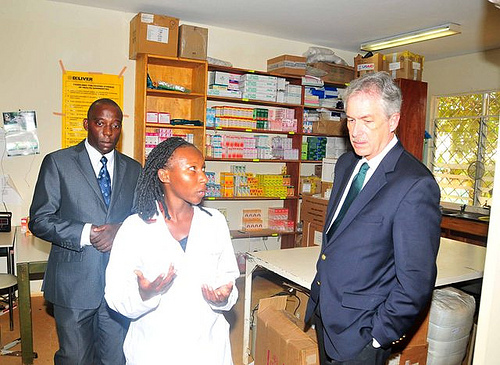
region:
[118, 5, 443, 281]
Wooden storage shelves with many objects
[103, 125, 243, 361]
Woman in white lab coat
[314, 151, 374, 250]
Turquoise blue men's neck tie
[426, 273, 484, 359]
White wrapped bundle under table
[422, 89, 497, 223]
Latticed window with view of green tree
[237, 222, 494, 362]
White lab table with knicks in paint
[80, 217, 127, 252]
Man's hands clasped together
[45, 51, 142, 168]
Orange poster with orange tape on the wall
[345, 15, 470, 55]
Flourescent light on ceiling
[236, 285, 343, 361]
Partially opened brown cardboard box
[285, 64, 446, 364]
person in a room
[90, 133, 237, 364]
person in a room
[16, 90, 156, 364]
person in a room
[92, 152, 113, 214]
blue tie with white spots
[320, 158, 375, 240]
shiny teal colored tie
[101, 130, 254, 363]
woman with white shirt on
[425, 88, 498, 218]
window with bars over it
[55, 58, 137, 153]
yellow sign with black writing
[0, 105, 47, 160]
small poster on the wall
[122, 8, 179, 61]
cardboard box on a shelf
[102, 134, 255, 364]
woman in white shirt gesturing with hands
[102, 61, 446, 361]
woman in white shirt talking to man in suit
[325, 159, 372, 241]
green tie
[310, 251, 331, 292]
gold buttons on front of blue suit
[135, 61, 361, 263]
line of ceiling height wooden bookshelves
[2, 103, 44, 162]
small poster on wall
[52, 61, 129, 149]
large yellow poster taped to wall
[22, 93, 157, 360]
man in grey suit and blue tie behind woman in white shirt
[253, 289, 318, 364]
open cardboard box under table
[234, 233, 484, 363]
white table in room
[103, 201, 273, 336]
woman has white shirt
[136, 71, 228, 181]
brown shelves behind woman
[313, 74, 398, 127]
man has grey hair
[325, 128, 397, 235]
man has dark blue tie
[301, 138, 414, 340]
man wears blue blazer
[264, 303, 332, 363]
brown box under table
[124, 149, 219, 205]
woman has dark hair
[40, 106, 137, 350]
man stands behind woman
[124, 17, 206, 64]
two boxes on shelves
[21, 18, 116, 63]
white wall next to shelves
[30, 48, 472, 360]
people that are standing inside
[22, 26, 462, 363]
three people standing inside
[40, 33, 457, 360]
three people in a room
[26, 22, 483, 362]
people in a room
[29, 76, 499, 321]
people standing in a room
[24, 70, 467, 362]
three people standing in a room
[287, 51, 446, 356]
a man with gray hair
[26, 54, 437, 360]
two men wearing suits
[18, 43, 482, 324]
two men wearing ties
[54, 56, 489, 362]
two men wearing suit and tie